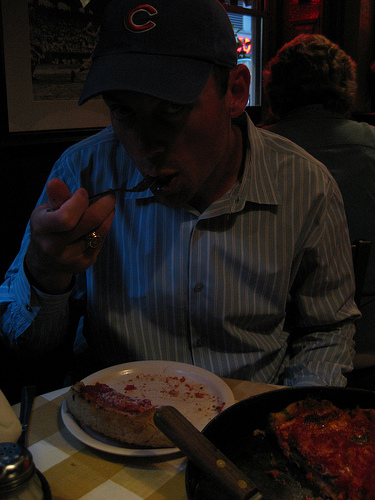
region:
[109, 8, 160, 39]
chicago cubs hat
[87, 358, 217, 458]
a half eaten piece of pizza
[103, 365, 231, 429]
a half full plate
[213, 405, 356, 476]
what seems to be a chicago pizza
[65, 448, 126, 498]
checkered print on the table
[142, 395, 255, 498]
a knife handle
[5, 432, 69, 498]
a parmesean dispenser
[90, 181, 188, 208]
the fork in the man's mouth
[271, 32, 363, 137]
the women in the back hair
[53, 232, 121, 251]
the man's ring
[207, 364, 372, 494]
pizza on black platter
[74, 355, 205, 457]
food on white plate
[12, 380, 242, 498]
food on table with yellow white table cloth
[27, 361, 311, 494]
yellow white checkered table cloth on table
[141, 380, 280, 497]
serving knife on platter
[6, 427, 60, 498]
grated cheese in clear holder with silver top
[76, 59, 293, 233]
man eating with fork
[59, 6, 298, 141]
man wearing blue ball cap with red c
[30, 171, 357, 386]
man in blue striped shirt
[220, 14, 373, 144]
woman sitting behind man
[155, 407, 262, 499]
A brown knife handle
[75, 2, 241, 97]
A baseball cap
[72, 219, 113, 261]
Ring on man's finger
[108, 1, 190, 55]
Chicago cubs logo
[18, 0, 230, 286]
A man eating food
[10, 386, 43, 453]
Silverware on table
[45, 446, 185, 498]
yellow and white tablecloth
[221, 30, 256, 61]
Neon sign outside window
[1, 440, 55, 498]
Shaker of grated cheese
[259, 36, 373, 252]
Women in blouse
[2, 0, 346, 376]
The man is wearing a ring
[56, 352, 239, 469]
There is a white plate with some food on it.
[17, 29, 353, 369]
The man is wearing a cap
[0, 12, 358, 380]
The man is wearing a blue and white shirt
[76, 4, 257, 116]
The cap has a red c on it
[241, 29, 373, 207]
There is a woman in the background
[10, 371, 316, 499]
The tablecloth is white and yellow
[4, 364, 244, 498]
The table cloth has squares on it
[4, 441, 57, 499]
There is a parmesean shaker on the table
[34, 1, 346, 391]
The man has a fork in his mouth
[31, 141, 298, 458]
man eating pizza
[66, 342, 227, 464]
pizza crust on white plate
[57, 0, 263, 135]
man wearing a blue hat with a C on it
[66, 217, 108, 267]
man wearing a gold ring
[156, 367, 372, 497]
pan of deep dish pizza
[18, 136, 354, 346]
blue dress shirt with white stripes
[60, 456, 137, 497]
gold and white gingham table cloth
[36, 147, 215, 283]
man holding a fork to his mouth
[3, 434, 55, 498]
small bottle of Parmesan cheese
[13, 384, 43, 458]
silver knife on table